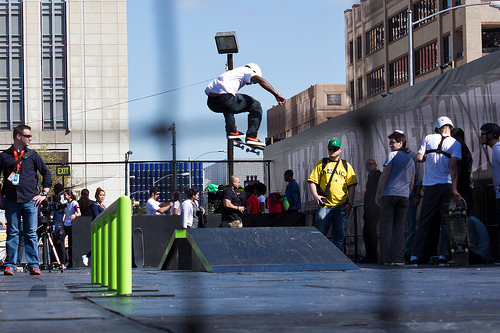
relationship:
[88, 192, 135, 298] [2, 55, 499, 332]
railing in skateboard park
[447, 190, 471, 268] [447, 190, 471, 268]
skateboard holding skateboard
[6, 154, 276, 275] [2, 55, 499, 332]
fence surrounds skateboard park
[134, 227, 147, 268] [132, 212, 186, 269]
skateboard leans against wall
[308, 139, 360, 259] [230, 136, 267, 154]
man watches skateboard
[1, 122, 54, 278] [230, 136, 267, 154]
man watches skateboard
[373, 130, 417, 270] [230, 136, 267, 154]
man watches skateboard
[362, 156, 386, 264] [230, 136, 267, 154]
man watches skateboard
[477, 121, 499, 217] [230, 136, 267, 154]
man watches skateboard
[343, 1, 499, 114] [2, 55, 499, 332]
building near skateboard park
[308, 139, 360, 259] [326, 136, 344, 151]
man wears hat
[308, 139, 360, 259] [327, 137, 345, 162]
man has head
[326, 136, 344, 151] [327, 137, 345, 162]
hat on head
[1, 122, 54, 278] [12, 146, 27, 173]
man wears lanyard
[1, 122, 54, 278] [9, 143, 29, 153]
man has neck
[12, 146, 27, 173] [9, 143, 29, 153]
lanyard around neck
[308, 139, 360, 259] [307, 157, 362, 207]
man wears shirt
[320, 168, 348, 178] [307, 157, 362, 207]
graphic on shirt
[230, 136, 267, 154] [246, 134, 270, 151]
skateboard wears shoe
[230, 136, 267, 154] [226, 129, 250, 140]
skateboard wears shoe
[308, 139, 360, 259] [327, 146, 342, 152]
man wears sunglasses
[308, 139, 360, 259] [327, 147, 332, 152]
man has eye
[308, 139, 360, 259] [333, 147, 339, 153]
man has eye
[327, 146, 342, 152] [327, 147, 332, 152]
sunglasses cover eye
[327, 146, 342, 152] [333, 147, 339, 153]
sunglasses cover eye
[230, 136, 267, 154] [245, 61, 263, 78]
skateboard wears helmet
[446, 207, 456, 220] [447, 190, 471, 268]
wheel on skateboard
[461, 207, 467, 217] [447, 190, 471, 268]
wheel on skateboard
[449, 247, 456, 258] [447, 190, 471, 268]
wheel on skateboard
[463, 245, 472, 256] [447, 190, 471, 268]
wheel on skateboard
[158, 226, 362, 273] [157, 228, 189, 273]
skateboard ramp has side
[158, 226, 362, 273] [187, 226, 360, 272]
skateboard ramp has side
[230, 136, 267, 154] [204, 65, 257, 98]
skateboard wears shirt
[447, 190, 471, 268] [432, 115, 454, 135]
skateboard wears helmet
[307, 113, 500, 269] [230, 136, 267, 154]
people are watching skateboard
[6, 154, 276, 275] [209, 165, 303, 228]
fence behind people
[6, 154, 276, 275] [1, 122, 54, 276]
fence behind man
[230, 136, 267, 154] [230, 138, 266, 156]
skateboard on skateboard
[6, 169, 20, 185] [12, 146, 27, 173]
id on lanyard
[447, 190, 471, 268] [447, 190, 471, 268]
skateboard holds skateboard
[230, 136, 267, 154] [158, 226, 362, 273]
skateboard jumping skateboard ramp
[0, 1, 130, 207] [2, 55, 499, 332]
building behind skateboard park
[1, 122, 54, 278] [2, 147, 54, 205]
man wears shirt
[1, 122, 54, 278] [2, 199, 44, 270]
man wears jeans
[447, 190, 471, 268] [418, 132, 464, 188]
skateboard wears shirt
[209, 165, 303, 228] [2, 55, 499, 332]
people are in skateboard park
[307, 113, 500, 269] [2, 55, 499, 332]
people are in skateboard park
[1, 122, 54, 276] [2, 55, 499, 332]
man are in skateboard park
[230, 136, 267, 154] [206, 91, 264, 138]
skateboard wears jeans